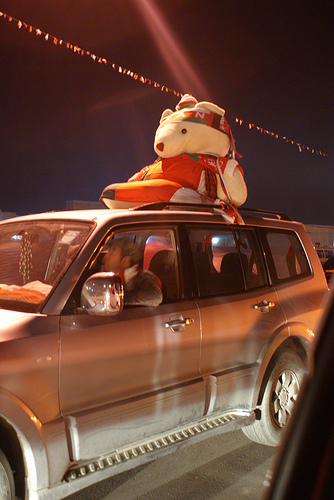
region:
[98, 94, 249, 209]
Stuffed animal sitting on top of car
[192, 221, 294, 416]
Left rear door of suv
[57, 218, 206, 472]
Driver's door of suv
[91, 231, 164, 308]
Man driving red suv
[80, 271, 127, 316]
Left side view mirrow of red suv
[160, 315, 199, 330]
Handle on driver's door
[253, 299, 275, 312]
Handle on left read door of red suv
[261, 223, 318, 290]
Back left side window of red suv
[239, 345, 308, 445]
Left read tire of red suv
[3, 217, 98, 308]
Front windshield of red suv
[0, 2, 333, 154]
A string of colorful lights in the background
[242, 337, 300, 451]
A tire on a car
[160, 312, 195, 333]
A front car door handle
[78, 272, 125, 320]
A car side mirror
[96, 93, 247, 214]
A teddy bear dressed up and tied to the top of a car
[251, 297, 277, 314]
A back car door handle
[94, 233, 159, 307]
A person driving a car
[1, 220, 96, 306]
A front windshield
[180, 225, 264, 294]
A back seat car window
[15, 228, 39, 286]
Beads hanging off of a rearview mirror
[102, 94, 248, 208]
a large white teddy bear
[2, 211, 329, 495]
a silver SUV on road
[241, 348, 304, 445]
a rear vehicle tire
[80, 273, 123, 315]
a rear view mirror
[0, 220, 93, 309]
a vehicle front windshield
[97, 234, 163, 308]
a man driving car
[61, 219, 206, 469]
a driver side door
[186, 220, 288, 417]
a driver side passenger door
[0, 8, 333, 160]
a red flag banner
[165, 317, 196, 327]
a driver's door handle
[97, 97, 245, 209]
Inflatable white polar bear decoration.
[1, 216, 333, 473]
Silver SUV with salted tires.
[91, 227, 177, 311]
Man in gray coat and red hat.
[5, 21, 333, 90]
Dark blue night sky.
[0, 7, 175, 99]
Decorative flag string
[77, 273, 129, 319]
Gray side view mirror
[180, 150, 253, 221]
Giant red and green scarf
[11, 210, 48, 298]
Decorative rear view mirror tinsel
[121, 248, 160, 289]
Red and white winter scarf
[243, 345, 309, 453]
Black car tire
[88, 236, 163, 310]
Man driving vehicle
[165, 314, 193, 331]
Driver door handle on vehicle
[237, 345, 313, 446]
Rear left tire on vehicle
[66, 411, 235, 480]
Running board on side of vehicle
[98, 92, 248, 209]
Stuffed animal on top of vehicle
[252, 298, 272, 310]
Rear door handle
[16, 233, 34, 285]
Rear-view mirror accessory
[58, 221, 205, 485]
Driver door on vehicle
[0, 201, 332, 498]
Large tan vehicle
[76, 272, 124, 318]
Driver side mirror